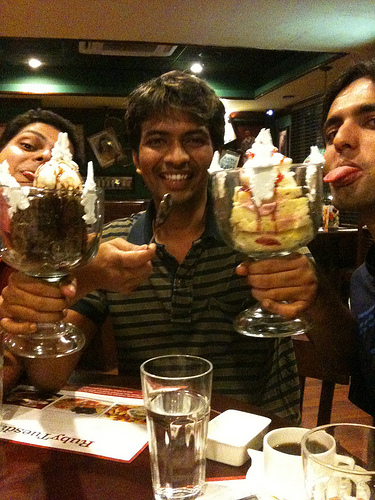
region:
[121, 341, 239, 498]
glass full of water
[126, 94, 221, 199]
man with a smile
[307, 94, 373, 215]
man sticking his tongue out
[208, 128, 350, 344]
ice cream sundae glass dish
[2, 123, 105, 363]
ice cream sundae glass dish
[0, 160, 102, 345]
hands holding ice cream dish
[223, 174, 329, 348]
hand holding ice cream dish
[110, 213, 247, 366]
striped shirt with a collar and buttons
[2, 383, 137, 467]
Ruby Tuesday's place mat on a table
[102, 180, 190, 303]
hand holding a spoon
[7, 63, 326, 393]
Man holding two desserts.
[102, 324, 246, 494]
Tall glass holding water.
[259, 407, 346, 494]
Nearly full white coffee cup.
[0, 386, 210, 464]
Menu from American restaurant.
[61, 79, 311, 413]
Man wearing green shirt with blue stripes.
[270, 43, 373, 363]
Man sticking his tongue out.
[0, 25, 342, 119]
Indentation in ceiling with green paint.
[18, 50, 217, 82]
Spotlights in ceiling.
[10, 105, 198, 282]
Man holding a spoon.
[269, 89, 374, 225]
Brown blinds on a window.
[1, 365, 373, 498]
Round brown table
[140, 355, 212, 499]
Glass of water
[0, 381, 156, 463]
Place mat with the restaurant name written on it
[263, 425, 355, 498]
White cup of coffee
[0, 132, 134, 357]
Chocolate dessert on the left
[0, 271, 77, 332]
Man's right hand holding the chocolate dessert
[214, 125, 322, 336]
Vanilla dessert on the right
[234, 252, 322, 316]
Man's left hand holding the vanilla dessert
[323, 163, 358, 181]
Man's stuck out tongue on the right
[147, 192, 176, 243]
Silver spoon held up in the center of the scene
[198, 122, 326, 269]
A dessert in a clear bowl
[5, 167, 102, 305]
A dessert in a clear glass bowl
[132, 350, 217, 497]
A glass of water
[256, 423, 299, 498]
A white coffee cup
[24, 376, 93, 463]
A menu on a table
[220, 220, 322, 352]
A hand holding a bowl of dessert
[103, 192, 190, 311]
A hand holding a spoon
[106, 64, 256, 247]
A man with a smile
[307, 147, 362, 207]
The tongue of a man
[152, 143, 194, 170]
The nose of a man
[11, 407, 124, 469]
Ruby Tuesday paper menu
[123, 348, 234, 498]
Tall glass of water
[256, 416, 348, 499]
Small mug of coffee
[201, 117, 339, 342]
Ice cream and cake dessert in tall glass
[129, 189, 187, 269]
Silver spoon in a man's hand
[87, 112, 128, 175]
Framed picture in the background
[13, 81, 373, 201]
Three young man smiling for the camera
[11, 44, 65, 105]
Spotlight on the ceiling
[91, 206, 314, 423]
Green and navy striped polo shirt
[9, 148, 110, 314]
Chocolate cake and vanilla ice cream dessert